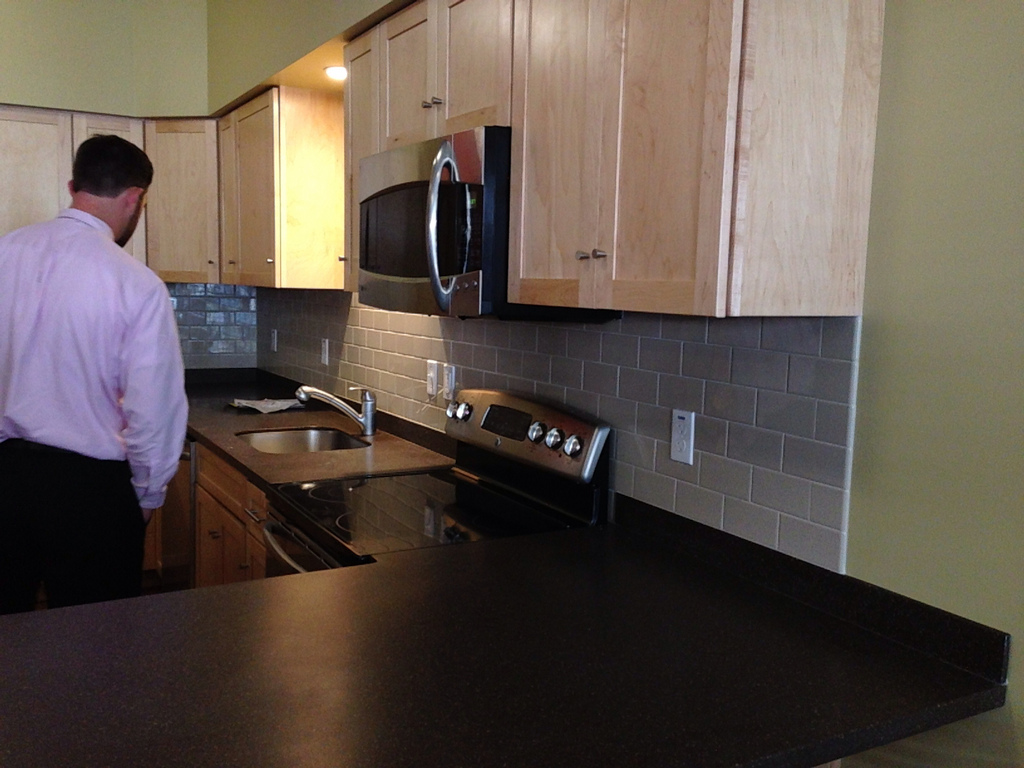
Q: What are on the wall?
A: Tiles.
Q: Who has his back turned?
A: A man.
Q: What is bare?
A: Countertop.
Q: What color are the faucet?
A: Silver.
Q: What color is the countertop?
A: Black.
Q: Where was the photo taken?
A: In a house.